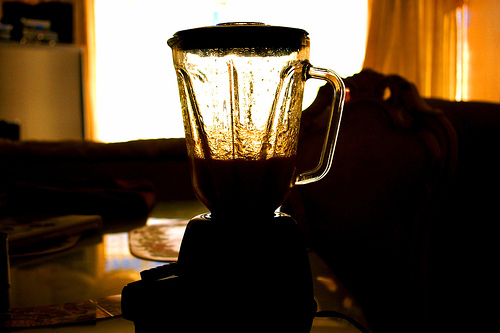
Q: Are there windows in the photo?
A: Yes, there is a window.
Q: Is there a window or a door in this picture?
A: Yes, there is a window.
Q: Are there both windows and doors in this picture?
A: No, there is a window but no doors.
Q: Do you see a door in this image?
A: No, there are no doors.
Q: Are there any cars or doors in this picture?
A: No, there are no doors or cars.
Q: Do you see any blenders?
A: Yes, there is a blender.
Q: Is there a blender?
A: Yes, there is a blender.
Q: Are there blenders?
A: Yes, there is a blender.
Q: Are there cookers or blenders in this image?
A: Yes, there is a blender.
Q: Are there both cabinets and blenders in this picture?
A: No, there is a blender but no cabinets.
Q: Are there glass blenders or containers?
A: Yes, there is a glass blender.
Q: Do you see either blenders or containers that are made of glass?
A: Yes, the blender is made of glass.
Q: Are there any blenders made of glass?
A: Yes, there is a blender that is made of glass.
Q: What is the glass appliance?
A: The appliance is a blender.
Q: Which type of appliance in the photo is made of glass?
A: The appliance is a blender.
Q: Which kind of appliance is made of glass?
A: The appliance is a blender.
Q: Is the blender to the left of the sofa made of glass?
A: Yes, the blender is made of glass.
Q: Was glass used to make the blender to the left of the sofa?
A: Yes, the blender is made of glass.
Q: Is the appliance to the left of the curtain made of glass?
A: Yes, the blender is made of glass.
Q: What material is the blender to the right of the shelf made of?
A: The blender is made of glass.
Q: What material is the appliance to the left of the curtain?
A: The blender is made of glass.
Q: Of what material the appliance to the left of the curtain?
A: The blender is made of glass.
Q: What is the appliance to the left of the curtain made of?
A: The blender is made of glass.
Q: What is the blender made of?
A: The blender is made of glass.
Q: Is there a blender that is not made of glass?
A: No, there is a blender but it is made of glass.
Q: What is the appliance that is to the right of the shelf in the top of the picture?
A: The appliance is a blender.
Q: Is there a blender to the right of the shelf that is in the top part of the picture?
A: Yes, there is a blender to the right of the shelf.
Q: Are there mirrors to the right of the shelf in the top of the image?
A: No, there is a blender to the right of the shelf.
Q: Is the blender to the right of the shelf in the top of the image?
A: Yes, the blender is to the right of the shelf.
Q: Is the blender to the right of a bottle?
A: No, the blender is to the right of the shelf.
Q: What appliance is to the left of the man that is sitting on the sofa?
A: The appliance is a blender.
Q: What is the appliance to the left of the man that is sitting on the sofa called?
A: The appliance is a blender.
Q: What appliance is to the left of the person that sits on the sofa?
A: The appliance is a blender.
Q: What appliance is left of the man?
A: The appliance is a blender.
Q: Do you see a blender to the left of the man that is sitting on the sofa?
A: Yes, there is a blender to the left of the man.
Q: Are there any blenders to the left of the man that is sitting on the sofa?
A: Yes, there is a blender to the left of the man.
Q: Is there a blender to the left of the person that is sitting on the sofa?
A: Yes, there is a blender to the left of the man.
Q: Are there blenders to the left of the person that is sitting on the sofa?
A: Yes, there is a blender to the left of the man.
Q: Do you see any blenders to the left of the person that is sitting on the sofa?
A: Yes, there is a blender to the left of the man.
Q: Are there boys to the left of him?
A: No, there is a blender to the left of the man.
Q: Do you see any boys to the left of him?
A: No, there is a blender to the left of the man.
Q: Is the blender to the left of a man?
A: Yes, the blender is to the left of a man.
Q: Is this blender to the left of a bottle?
A: No, the blender is to the left of a man.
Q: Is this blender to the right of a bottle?
A: No, the blender is to the right of the shelf.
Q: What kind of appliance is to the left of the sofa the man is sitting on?
A: The appliance is a blender.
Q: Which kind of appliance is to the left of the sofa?
A: The appliance is a blender.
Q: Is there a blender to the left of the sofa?
A: Yes, there is a blender to the left of the sofa.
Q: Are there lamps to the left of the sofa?
A: No, there is a blender to the left of the sofa.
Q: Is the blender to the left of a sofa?
A: Yes, the blender is to the left of a sofa.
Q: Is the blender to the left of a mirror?
A: No, the blender is to the left of a sofa.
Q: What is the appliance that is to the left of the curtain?
A: The appliance is a blender.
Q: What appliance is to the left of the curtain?
A: The appliance is a blender.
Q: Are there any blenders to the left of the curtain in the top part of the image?
A: Yes, there is a blender to the left of the curtain.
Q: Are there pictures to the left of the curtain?
A: No, there is a blender to the left of the curtain.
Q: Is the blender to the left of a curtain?
A: Yes, the blender is to the left of a curtain.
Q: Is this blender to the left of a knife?
A: No, the blender is to the left of a curtain.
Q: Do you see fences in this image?
A: No, there are no fences.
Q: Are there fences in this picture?
A: No, there are no fences.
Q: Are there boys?
A: No, there are no boys.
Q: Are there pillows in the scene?
A: No, there are no pillows.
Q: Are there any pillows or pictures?
A: No, there are no pillows or pictures.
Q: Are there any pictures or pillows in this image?
A: No, there are no pillows or pictures.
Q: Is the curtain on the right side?
A: Yes, the curtain is on the right of the image.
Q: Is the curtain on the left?
A: No, the curtain is on the right of the image.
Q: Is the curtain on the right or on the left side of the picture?
A: The curtain is on the right of the image.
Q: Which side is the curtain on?
A: The curtain is on the right of the image.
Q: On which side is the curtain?
A: The curtain is on the right of the image.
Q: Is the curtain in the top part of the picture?
A: Yes, the curtain is in the top of the image.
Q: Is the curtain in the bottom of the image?
A: No, the curtain is in the top of the image.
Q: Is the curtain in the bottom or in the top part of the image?
A: The curtain is in the top of the image.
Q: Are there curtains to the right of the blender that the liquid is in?
A: Yes, there is a curtain to the right of the blender.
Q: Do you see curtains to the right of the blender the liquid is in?
A: Yes, there is a curtain to the right of the blender.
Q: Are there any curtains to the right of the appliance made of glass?
A: Yes, there is a curtain to the right of the blender.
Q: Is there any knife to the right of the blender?
A: No, there is a curtain to the right of the blender.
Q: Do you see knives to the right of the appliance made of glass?
A: No, there is a curtain to the right of the blender.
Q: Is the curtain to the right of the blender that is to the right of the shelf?
A: Yes, the curtain is to the right of the blender.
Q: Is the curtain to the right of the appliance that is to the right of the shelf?
A: Yes, the curtain is to the right of the blender.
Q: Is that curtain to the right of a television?
A: No, the curtain is to the right of the blender.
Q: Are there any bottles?
A: No, there are no bottles.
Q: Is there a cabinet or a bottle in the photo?
A: No, there are no bottles or cabinets.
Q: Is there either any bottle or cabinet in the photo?
A: No, there are no bottles or cabinets.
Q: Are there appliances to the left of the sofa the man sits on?
A: Yes, there is an appliance to the left of the sofa.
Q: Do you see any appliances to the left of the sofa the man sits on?
A: Yes, there is an appliance to the left of the sofa.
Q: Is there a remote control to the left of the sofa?
A: No, there is an appliance to the left of the sofa.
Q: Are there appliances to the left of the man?
A: Yes, there is an appliance to the left of the man.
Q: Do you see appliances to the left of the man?
A: Yes, there is an appliance to the left of the man.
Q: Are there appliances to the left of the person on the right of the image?
A: Yes, there is an appliance to the left of the man.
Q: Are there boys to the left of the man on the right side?
A: No, there is an appliance to the left of the man.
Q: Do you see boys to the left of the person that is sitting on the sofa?
A: No, there is an appliance to the left of the man.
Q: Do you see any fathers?
A: No, there are no fathers.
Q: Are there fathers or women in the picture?
A: No, there are no fathers or women.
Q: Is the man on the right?
A: Yes, the man is on the right of the image.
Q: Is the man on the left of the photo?
A: No, the man is on the right of the image.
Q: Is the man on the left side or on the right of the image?
A: The man is on the right of the image.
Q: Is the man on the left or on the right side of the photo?
A: The man is on the right of the image.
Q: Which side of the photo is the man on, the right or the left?
A: The man is on the right of the image.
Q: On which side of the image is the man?
A: The man is on the right of the image.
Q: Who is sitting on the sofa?
A: The man is sitting on the sofa.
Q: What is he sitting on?
A: The man is sitting on the sofa.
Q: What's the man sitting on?
A: The man is sitting on the sofa.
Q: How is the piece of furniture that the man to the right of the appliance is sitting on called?
A: The piece of furniture is a sofa.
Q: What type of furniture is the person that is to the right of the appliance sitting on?
A: The man is sitting on the sofa.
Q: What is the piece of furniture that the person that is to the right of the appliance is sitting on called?
A: The piece of furniture is a sofa.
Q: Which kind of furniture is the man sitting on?
A: The man is sitting on the sofa.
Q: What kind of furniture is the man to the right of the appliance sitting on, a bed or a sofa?
A: The man is sitting on a sofa.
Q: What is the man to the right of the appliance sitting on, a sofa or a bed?
A: The man is sitting on a sofa.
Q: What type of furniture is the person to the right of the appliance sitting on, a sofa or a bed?
A: The man is sitting on a sofa.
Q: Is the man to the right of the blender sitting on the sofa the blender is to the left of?
A: Yes, the man is sitting on the sofa.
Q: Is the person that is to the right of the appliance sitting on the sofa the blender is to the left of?
A: Yes, the man is sitting on the sofa.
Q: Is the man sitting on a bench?
A: No, the man is sitting on the sofa.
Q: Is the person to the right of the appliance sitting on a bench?
A: No, the man is sitting on the sofa.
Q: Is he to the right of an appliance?
A: Yes, the man is to the right of an appliance.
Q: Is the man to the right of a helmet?
A: No, the man is to the right of an appliance.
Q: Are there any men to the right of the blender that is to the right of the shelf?
A: Yes, there is a man to the right of the blender.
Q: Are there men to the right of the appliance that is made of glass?
A: Yes, there is a man to the right of the blender.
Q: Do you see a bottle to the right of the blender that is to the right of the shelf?
A: No, there is a man to the right of the blender.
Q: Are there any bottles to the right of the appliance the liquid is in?
A: No, there is a man to the right of the blender.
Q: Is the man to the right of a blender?
A: Yes, the man is to the right of a blender.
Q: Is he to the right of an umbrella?
A: No, the man is to the right of a blender.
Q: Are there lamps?
A: No, there are no lamps.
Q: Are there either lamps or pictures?
A: No, there are no lamps or pictures.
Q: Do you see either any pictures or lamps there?
A: No, there are no lamps or pictures.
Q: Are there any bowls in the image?
A: No, there are no bowls.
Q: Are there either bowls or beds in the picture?
A: No, there are no bowls or beds.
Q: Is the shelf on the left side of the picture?
A: Yes, the shelf is on the left of the image.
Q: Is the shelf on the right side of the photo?
A: No, the shelf is on the left of the image.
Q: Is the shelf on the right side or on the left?
A: The shelf is on the left of the image.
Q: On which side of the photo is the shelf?
A: The shelf is on the left of the image.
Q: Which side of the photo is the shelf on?
A: The shelf is on the left of the image.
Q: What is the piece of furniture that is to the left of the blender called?
A: The piece of furniture is a shelf.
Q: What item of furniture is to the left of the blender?
A: The piece of furniture is a shelf.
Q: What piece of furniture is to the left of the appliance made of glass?
A: The piece of furniture is a shelf.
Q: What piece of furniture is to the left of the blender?
A: The piece of furniture is a shelf.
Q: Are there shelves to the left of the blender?
A: Yes, there is a shelf to the left of the blender.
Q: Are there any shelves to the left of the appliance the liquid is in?
A: Yes, there is a shelf to the left of the blender.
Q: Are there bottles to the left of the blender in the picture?
A: No, there is a shelf to the left of the blender.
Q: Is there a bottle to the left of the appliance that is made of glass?
A: No, there is a shelf to the left of the blender.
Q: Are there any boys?
A: No, there are no boys.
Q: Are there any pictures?
A: No, there are no pictures.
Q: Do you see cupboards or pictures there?
A: No, there are no pictures or cupboards.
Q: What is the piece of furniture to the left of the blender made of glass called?
A: The piece of furniture is a shelf.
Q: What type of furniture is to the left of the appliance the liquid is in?
A: The piece of furniture is a shelf.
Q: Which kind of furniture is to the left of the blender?
A: The piece of furniture is a shelf.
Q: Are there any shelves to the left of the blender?
A: Yes, there is a shelf to the left of the blender.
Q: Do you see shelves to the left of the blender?
A: Yes, there is a shelf to the left of the blender.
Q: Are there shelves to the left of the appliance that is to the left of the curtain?
A: Yes, there is a shelf to the left of the blender.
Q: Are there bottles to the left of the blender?
A: No, there is a shelf to the left of the blender.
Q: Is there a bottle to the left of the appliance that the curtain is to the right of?
A: No, there is a shelf to the left of the blender.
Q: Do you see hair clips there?
A: No, there are no hair clips.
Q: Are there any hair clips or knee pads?
A: No, there are no hair clips or knee pads.